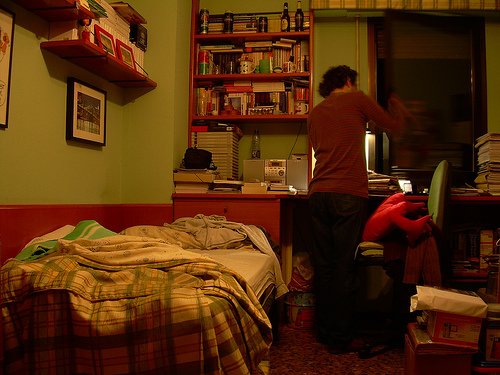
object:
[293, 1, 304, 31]
beet bottles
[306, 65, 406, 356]
boy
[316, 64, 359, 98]
brown hair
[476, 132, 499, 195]
stack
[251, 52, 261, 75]
book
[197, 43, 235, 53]
book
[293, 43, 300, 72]
book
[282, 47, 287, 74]
book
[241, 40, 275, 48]
book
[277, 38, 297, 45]
book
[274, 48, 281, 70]
book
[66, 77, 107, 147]
artwork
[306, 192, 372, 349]
jeans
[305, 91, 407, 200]
shirt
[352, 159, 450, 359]
chair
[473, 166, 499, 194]
books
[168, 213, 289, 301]
pants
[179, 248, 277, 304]
bedspread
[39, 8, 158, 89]
shelf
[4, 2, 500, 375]
bedroom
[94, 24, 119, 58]
frames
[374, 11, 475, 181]
window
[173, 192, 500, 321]
desk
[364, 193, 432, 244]
pillow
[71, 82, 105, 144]
picture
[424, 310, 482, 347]
box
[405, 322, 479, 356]
box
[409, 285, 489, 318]
paper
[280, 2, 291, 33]
bottles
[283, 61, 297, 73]
cans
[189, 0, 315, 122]
shelf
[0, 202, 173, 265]
paneling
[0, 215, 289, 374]
bed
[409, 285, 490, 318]
boxes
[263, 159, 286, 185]
stereo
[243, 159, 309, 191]
speakers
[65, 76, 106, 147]
frame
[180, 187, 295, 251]
table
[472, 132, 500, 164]
books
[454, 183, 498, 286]
table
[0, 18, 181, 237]
wall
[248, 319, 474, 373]
floor